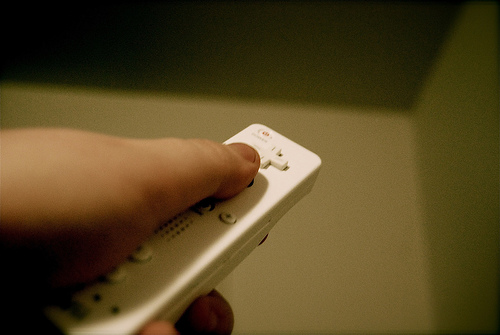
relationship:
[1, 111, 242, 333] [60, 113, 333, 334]
hand holding remote control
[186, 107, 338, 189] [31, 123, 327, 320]
thumb remote holding remote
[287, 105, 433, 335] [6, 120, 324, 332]
light reflecting remote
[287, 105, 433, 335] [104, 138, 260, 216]
light shining finger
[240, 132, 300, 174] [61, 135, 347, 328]
direction control on remote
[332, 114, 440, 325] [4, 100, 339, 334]
light on control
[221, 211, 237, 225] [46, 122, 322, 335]
button on control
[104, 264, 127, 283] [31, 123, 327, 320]
button on remote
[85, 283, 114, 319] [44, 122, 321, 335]
light on controler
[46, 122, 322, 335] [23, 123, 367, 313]
control in hand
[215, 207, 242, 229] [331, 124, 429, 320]
button on remote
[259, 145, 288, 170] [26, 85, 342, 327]
button on remote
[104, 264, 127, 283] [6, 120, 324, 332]
button on remote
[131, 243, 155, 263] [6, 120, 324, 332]
button on remote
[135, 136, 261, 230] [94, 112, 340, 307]
finger on controller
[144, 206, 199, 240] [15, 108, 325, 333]
holes in controller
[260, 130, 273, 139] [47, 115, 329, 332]
button on controler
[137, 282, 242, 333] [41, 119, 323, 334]
fingers under under controller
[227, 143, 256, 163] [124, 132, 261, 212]
nail on finger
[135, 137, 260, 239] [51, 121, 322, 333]
finger grabbing remote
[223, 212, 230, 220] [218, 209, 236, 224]
plus sign on button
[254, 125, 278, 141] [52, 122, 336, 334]
button on control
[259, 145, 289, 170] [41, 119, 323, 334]
direction control on controller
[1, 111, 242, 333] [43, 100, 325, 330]
hand on controller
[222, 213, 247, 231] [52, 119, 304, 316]
screw holding cover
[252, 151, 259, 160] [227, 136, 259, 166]
dirt under nail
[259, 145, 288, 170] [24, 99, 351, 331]
button on remote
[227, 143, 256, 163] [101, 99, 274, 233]
nail on thumb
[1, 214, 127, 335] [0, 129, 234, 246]
shadow of hand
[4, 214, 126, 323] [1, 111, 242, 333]
shadow on hand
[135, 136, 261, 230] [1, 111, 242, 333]
finger on hand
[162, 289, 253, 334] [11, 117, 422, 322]
finger on remote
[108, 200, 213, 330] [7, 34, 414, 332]
button on remote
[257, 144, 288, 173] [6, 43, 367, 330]
button on remote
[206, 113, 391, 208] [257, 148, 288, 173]
cross shape on button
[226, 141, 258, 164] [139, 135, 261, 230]
nail on thumb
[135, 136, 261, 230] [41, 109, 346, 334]
finger on controller